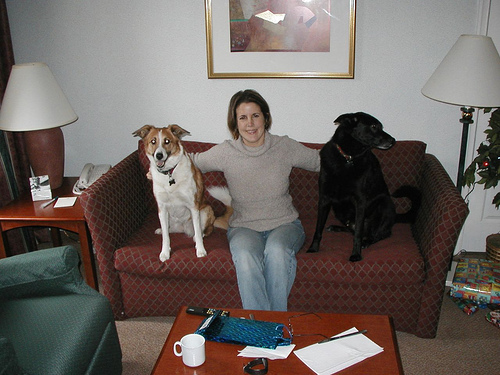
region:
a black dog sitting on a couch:
[302, 106, 403, 276]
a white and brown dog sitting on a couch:
[125, 112, 217, 272]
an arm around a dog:
[290, 127, 365, 192]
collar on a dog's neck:
[145, 155, 190, 180]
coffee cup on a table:
[170, 330, 210, 370]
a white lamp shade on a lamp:
[420, 25, 495, 145]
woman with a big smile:
[222, 82, 272, 154]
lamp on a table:
[0, 40, 70, 190]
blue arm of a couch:
[10, 245, 80, 295]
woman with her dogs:
[125, 81, 395, 197]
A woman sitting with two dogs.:
[110, 85, 413, 288]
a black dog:
[304, 85, 434, 277]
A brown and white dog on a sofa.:
[106, 100, 232, 274]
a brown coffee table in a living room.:
[153, 295, 400, 370]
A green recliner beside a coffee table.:
[2, 208, 142, 368]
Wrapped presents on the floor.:
[452, 215, 498, 312]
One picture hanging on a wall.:
[188, 0, 389, 92]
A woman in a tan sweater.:
[190, 79, 307, 315]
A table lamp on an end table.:
[3, 49, 88, 215]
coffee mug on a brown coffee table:
[172, 333, 214, 370]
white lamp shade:
[2, 62, 85, 130]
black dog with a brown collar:
[311, 95, 415, 266]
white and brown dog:
[115, 111, 225, 263]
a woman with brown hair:
[213, 85, 277, 149]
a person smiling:
[233, 122, 273, 141]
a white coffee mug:
[163, 315, 217, 365]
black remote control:
[187, 297, 232, 319]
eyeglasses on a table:
[276, 307, 344, 347]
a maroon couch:
[90, 170, 466, 327]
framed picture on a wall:
[188, 2, 380, 82]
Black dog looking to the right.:
[316, 110, 406, 251]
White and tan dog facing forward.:
[128, 118, 220, 260]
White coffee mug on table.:
[170, 326, 215, 372]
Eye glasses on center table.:
[283, 310, 333, 341]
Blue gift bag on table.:
[201, 308, 295, 348]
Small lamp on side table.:
[11, 90, 56, 197]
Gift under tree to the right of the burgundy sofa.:
[453, 253, 498, 313]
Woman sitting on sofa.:
[201, 90, 329, 310]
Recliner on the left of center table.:
[0, 254, 131, 372]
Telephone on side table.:
[80, 155, 110, 195]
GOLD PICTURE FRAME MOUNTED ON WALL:
[169, 8, 373, 100]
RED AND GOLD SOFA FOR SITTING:
[97, 161, 459, 312]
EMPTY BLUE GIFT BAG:
[199, 297, 301, 351]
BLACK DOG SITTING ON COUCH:
[292, 99, 417, 278]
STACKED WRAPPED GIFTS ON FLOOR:
[428, 215, 497, 347]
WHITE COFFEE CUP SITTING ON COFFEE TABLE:
[143, 321, 237, 366]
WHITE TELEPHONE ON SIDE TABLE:
[45, 146, 132, 229]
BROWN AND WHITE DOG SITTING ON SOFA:
[130, 118, 207, 286]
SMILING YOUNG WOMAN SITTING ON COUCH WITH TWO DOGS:
[133, 91, 405, 270]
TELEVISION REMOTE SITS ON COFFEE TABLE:
[155, 281, 267, 322]